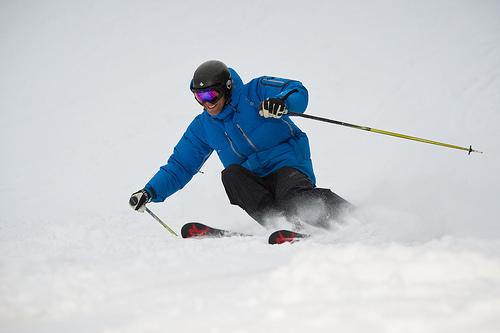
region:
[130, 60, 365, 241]
a skier making a turn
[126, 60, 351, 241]
a man making a turn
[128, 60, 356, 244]
a person making a turn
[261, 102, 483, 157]
the left hand holding a ski pole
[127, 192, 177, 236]
right hand holding a ski pole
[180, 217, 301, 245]
front tips of the skis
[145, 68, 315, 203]
the blue jacket on the skier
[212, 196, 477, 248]
snow being kicked up by skier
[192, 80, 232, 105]
a pair of goggles on the skier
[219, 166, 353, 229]
black snow pants on the skier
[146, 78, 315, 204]
blue jacket of skier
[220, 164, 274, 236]
black pant leg of skier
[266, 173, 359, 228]
black pant leg of skier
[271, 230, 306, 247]
bottom of ski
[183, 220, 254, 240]
bottom of ski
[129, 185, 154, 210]
hand of skier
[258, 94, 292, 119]
hand of skier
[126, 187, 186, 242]
hand holding ski pole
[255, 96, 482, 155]
hand holding ski pole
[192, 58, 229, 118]
black helmet on skier in the snow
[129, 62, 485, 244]
the man is skiing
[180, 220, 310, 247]
the ski shoes have a red pattern underneath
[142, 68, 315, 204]
the coat is blue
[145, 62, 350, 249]
the man is wearing a helmet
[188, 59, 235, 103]
the helmet is black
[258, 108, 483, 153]
the bottom of the ski pole is yellow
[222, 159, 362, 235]
the pants are black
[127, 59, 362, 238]
the man is wearing black pants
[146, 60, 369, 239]
the man is wearing large goggles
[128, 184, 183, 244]
The man is holding a ski stick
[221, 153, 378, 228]
The man is wearing pants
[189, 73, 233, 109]
The man is wearing snow goggles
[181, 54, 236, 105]
The man has on a helmet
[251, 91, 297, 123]
The man is wearing gloves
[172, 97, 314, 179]
The color of the jacket is blue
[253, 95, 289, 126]
The gloves are black and white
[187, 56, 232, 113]
The helmet is the color black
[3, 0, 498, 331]
a skier in a blue jacket coming down a snowy slope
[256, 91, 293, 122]
a hand in a black glove trimmed in white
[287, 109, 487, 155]
a yellow and black ski pole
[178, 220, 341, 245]
a pair of black skis with red design on the bottom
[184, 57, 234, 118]
a person's head in a black helmet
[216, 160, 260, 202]
a bent right knee in black pants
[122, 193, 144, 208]
the black top of a ski pole with white lettering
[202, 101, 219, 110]
a person's lips and teeth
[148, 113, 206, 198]
an extended arm in a blue jacket